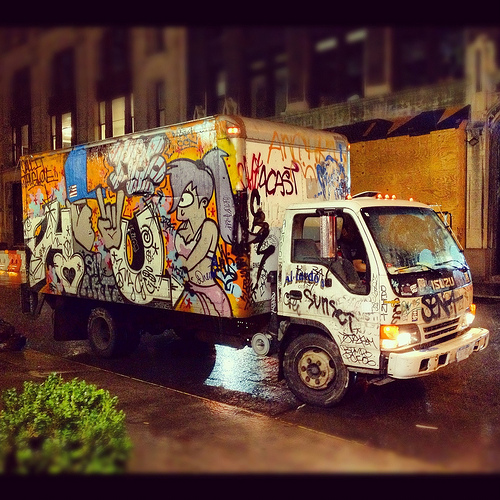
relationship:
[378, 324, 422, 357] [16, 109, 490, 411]
headlight of truck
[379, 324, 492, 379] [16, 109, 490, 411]
bumper of truck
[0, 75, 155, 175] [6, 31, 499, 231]
windows of building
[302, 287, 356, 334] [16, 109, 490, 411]
sunset on truck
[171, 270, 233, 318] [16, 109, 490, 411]
graffiti on truck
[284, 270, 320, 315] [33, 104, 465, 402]
graffiti on truck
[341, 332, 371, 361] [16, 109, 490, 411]
graffiti on truck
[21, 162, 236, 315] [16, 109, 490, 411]
graffiti on truck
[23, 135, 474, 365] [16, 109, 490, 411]
graffiti on truck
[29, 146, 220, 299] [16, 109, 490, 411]
graffiti on truck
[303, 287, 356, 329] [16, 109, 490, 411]
sunset on truck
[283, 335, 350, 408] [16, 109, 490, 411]
tire on truck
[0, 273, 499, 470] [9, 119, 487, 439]
pavement under truck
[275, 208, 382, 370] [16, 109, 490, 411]
door on truck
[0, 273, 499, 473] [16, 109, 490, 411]
pavement by truck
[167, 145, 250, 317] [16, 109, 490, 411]
character on truck